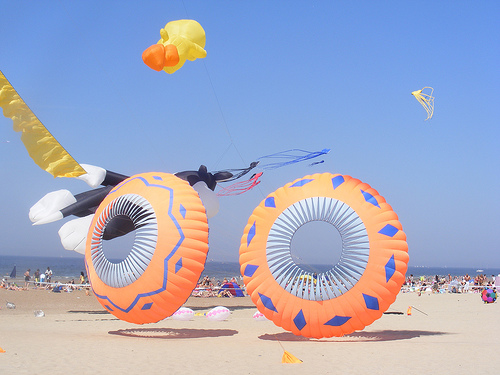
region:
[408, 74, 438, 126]
White kite flying in sky.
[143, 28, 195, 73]
Yellow kite flying in kite.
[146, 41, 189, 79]
Orange feet on kite in sky.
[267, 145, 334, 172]
Blue streamers on kite.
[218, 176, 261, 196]
Red streamers on kite in sky.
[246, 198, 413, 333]
Orange and blue kite on beach.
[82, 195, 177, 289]
Orange and blue kite on sand.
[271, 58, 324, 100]
Sky is blue and clear.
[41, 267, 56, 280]
Person wearing white shirt.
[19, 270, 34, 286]
Person wearing black shorts.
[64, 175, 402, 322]
these are the kites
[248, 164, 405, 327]
this is orange in color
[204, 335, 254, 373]
this is the beach sand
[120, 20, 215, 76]
the kite is on air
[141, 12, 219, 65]
the kite is on air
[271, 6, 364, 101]
the sky is clear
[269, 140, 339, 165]
the kits is wavy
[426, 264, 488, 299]
the beach is full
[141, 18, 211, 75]
A kite shaped like a bird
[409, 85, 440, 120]
A yellow kite with long tails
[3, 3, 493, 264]
A blue sky without clouds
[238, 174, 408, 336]
An orange, circular kite near the ground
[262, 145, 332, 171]
A blue kite with long tails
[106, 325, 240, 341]
A kite's shadow cast onto the ground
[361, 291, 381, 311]
Diamond shape on an orange kite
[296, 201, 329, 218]
Striped pattern on a kite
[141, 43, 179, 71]
Orange feet on a kite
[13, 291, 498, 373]
Brown sand at the beach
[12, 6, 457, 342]
A variety of kites at the beach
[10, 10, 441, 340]
A variety of kites at the beach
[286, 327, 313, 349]
edge of a shade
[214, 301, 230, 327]
aprt of a ground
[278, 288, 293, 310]
aprt of a line